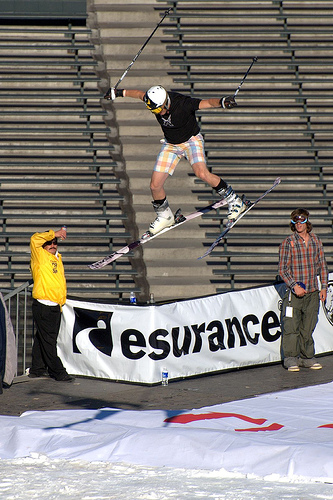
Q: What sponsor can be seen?
A: Esurance.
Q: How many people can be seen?
A: Three.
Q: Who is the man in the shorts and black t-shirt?
A: A contestant.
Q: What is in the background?
A: Stands.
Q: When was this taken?
A: During the day.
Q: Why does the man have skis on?
A: He is in a skiing competition.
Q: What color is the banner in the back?
A: Black and white.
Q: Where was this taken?
A: At a skiing competition.